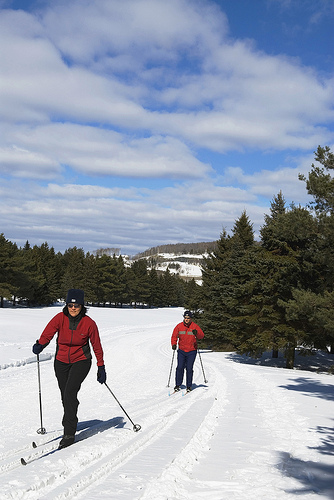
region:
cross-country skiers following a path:
[19, 284, 210, 472]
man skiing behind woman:
[26, 282, 206, 394]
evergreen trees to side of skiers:
[160, 169, 329, 386]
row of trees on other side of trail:
[0, 229, 195, 309]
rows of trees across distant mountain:
[121, 239, 212, 277]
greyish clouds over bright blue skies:
[44, 85, 216, 212]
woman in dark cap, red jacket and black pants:
[26, 285, 111, 446]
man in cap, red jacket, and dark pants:
[170, 299, 196, 391]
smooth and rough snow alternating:
[132, 379, 299, 454]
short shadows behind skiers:
[67, 378, 205, 444]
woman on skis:
[8, 287, 157, 472]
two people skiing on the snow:
[12, 297, 232, 474]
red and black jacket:
[30, 311, 112, 367]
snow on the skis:
[26, 445, 59, 462]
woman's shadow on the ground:
[56, 414, 131, 440]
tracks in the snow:
[116, 393, 183, 433]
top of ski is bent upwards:
[16, 455, 31, 465]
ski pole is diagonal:
[92, 369, 158, 439]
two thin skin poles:
[158, 336, 215, 392]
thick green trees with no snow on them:
[174, 188, 331, 371]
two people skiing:
[17, 284, 210, 464]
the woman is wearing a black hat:
[16, 283, 140, 460]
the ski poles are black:
[29, 343, 138, 434]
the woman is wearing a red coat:
[35, 308, 102, 365]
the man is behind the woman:
[18, 287, 213, 464]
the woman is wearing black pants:
[51, 357, 92, 444]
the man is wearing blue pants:
[172, 348, 203, 392]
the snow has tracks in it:
[31, 388, 212, 498]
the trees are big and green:
[188, 179, 333, 370]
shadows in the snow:
[271, 370, 333, 497]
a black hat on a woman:
[62, 285, 86, 305]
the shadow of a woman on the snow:
[73, 405, 130, 447]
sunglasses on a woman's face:
[65, 301, 81, 309]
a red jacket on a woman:
[38, 311, 106, 367]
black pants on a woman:
[54, 355, 92, 434]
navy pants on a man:
[172, 348, 197, 385]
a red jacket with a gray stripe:
[171, 320, 203, 350]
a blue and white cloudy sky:
[1, 1, 331, 254]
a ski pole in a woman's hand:
[30, 339, 48, 436]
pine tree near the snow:
[227, 233, 311, 353]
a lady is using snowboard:
[20, 411, 135, 464]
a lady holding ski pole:
[97, 373, 141, 432]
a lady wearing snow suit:
[43, 289, 112, 462]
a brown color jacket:
[40, 314, 100, 365]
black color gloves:
[95, 359, 105, 380]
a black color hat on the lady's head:
[63, 287, 85, 300]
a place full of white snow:
[116, 309, 150, 391]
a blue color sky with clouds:
[38, 141, 242, 212]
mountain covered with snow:
[143, 236, 234, 275]